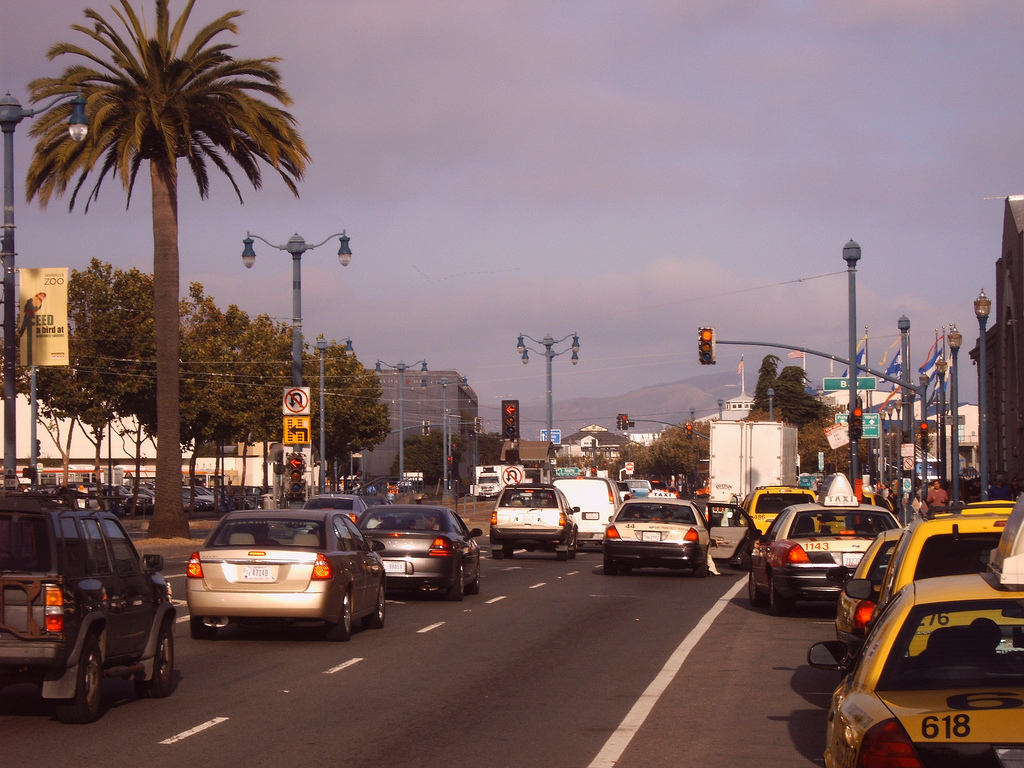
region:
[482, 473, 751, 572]
vehicles on the road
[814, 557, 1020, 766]
taxi cab on the road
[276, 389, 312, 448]
signs on the pole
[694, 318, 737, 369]
orange traffic light on a pole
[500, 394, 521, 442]
red traffic light above the vehicles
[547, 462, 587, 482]
green and white sign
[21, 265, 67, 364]
bird on the sign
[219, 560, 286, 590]
license plate on the car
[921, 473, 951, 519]
person walking on the sidewalk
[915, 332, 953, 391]
flags flying in the air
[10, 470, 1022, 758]
Multiple cars are on the road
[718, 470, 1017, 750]
five yellow taxi cabs on the side of the road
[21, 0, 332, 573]
large green palm tree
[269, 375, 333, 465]
two different street signs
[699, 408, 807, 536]
large white semi truck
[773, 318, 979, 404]
multiple flags flying in the air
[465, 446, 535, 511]
large white semi truck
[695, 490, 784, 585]
car door is open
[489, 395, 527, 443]
street light is red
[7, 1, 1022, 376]
The dark clouds on the horizon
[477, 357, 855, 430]
The mountain range nearly covered by the clouds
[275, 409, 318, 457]
The yellow left turn sign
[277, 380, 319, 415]
The no U-turn sign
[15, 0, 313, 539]
The large palm tree in the median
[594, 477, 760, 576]
The taxi with the passenger side door open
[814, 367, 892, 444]
The green street signs on poles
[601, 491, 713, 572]
A white taxi in a middle lane.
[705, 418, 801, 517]
A white semi truck.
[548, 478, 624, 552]
A white van in front of an suv.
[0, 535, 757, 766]
A dark grey two lane road with white lines.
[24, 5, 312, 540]
Largest palm tree with grey trunk.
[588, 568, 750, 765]
Thick white line going down the road.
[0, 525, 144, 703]
car on the road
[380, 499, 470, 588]
car on the road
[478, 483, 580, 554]
car on the road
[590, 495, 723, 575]
car on the road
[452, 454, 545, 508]
car on the road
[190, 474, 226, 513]
car on the road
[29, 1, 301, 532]
a large palm tree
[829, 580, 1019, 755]
a yellow taxi cab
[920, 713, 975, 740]
Number on a taxi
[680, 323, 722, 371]
Traffic light on a post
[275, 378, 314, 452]
Traffic signs on a post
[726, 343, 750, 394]
Flag on a building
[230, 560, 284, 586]
Plate on a car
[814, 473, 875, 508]
Taxi sign on a car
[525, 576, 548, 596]
White paint on the road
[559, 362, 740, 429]
Mountains in the background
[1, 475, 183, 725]
vehicle on the dark street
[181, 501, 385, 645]
vehicle on the dark street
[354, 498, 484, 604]
vehicle on the dark street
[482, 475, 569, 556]
vehicle on the dark street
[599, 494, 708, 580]
vehicle on the dark street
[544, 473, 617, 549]
vehicle on the dark street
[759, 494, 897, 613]
vehicle on the dark street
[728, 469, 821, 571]
vehicle on the dark street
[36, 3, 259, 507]
A tall palm tree next to the road.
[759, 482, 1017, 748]
A row of taxis at the curb.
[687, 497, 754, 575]
A person getting out of a taxi.